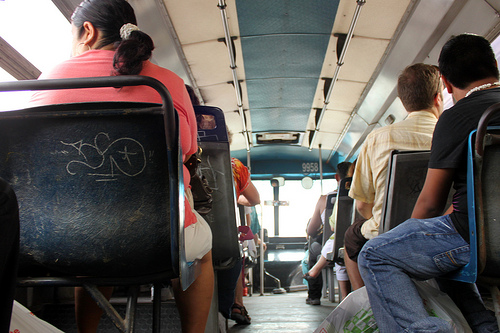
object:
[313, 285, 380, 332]
shopping bag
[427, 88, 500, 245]
shirt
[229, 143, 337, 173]
trim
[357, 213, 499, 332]
jeans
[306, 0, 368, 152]
hand rials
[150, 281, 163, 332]
legs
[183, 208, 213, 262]
shorts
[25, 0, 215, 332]
bus rider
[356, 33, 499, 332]
bus rider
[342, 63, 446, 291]
bus rider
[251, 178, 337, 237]
windshield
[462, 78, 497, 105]
necklace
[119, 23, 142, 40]
band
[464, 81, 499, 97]
necklace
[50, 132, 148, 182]
graffiti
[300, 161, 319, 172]
9958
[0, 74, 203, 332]
chair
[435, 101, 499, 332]
chair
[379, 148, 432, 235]
chair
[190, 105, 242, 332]
chair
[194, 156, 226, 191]
graffitti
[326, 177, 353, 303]
seat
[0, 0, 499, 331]
photo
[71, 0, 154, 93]
hair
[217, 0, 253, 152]
bar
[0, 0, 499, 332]
bus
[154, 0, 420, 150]
roof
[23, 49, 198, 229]
shirt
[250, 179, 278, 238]
window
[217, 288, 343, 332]
floor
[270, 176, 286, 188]
mirror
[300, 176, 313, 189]
mirror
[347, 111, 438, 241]
shirt